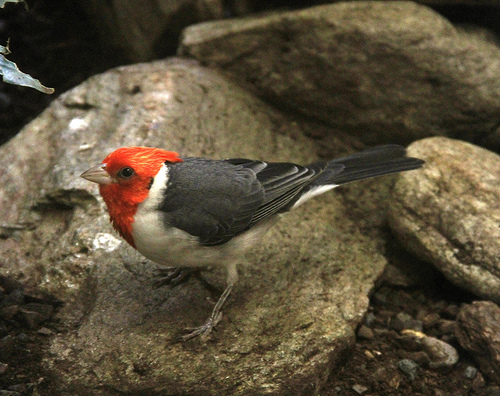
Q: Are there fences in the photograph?
A: No, there are no fences.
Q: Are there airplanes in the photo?
A: No, there are no airplanes.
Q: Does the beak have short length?
A: Yes, the beak is short.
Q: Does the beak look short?
A: Yes, the beak is short.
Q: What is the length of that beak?
A: The beak is short.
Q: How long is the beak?
A: The beak is short.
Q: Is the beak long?
A: No, the beak is short.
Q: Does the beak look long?
A: No, the beak is short.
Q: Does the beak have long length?
A: No, the beak is short.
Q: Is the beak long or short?
A: The beak is short.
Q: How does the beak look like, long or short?
A: The beak is short.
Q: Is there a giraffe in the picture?
A: No, there are no giraffes.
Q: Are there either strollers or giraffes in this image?
A: No, there are no giraffes or strollers.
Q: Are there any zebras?
A: No, there are no zebras.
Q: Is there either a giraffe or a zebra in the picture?
A: No, there are no zebras or giraffes.